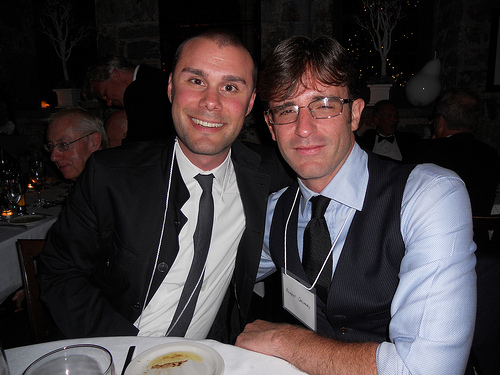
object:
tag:
[280, 267, 317, 332]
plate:
[126, 340, 225, 374]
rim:
[21, 352, 50, 375]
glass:
[21, 344, 115, 374]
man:
[235, 30, 475, 374]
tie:
[165, 173, 216, 339]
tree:
[38, 0, 90, 81]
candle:
[0, 208, 13, 219]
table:
[0, 179, 63, 303]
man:
[37, 18, 297, 347]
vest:
[269, 151, 417, 342]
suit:
[36, 139, 297, 347]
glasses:
[265, 95, 353, 125]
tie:
[303, 195, 332, 307]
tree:
[358, 0, 403, 82]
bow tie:
[374, 134, 399, 145]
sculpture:
[406, 49, 443, 107]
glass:
[3, 178, 26, 222]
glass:
[26, 164, 49, 208]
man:
[66, 50, 176, 150]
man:
[102, 108, 129, 148]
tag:
[137, 335, 170, 337]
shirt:
[375, 162, 478, 374]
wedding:
[0, 0, 500, 375]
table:
[2, 336, 308, 375]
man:
[42, 108, 107, 182]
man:
[357, 98, 416, 164]